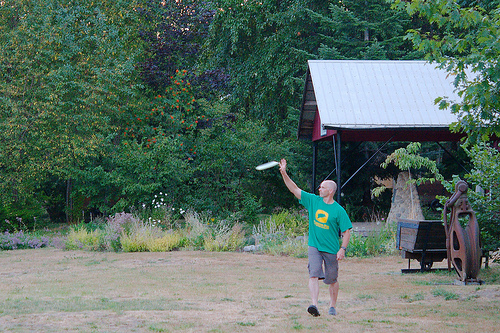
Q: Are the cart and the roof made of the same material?
A: No, the cart is made of wood and the roof is made of metal.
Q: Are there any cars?
A: No, there are no cars.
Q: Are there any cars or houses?
A: No, there are no cars or houses.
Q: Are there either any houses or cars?
A: No, there are no cars or houses.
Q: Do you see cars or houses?
A: No, there are no cars or houses.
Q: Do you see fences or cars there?
A: No, there are no cars or fences.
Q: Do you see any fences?
A: No, there are no fences.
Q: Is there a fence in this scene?
A: No, there are no fences.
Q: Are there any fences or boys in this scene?
A: No, there are no fences or boys.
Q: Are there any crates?
A: No, there are no crates.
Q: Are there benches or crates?
A: No, there are no crates or benches.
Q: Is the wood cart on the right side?
A: Yes, the cart is on the right of the image.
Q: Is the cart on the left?
A: No, the cart is on the right of the image.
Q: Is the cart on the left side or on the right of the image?
A: The cart is on the right of the image.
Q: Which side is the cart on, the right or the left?
A: The cart is on the right of the image.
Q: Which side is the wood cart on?
A: The cart is on the right of the image.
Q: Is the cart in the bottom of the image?
A: Yes, the cart is in the bottom of the image.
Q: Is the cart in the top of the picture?
A: No, the cart is in the bottom of the image.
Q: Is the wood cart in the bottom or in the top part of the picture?
A: The cart is in the bottom of the image.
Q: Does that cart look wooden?
A: Yes, the cart is wooden.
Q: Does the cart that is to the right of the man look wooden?
A: Yes, the cart is wooden.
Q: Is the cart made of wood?
A: Yes, the cart is made of wood.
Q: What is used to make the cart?
A: The cart is made of wood.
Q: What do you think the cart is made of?
A: The cart is made of wood.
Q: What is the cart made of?
A: The cart is made of wood.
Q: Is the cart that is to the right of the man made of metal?
A: No, the cart is made of wood.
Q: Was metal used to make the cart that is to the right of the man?
A: No, the cart is made of wood.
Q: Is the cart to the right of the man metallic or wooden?
A: The cart is wooden.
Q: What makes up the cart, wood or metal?
A: The cart is made of wood.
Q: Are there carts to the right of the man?
A: Yes, there is a cart to the right of the man.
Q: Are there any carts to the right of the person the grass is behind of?
A: Yes, there is a cart to the right of the man.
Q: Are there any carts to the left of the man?
A: No, the cart is to the right of the man.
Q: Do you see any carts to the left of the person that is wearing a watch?
A: No, the cart is to the right of the man.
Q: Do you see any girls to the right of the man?
A: No, there is a cart to the right of the man.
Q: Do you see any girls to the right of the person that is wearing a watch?
A: No, there is a cart to the right of the man.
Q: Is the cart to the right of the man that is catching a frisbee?
A: Yes, the cart is to the right of the man.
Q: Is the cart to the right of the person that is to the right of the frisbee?
A: Yes, the cart is to the right of the man.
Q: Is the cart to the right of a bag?
A: No, the cart is to the right of the man.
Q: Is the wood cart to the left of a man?
A: No, the cart is to the right of a man.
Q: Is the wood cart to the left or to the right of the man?
A: The cart is to the right of the man.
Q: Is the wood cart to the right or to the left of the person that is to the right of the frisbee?
A: The cart is to the right of the man.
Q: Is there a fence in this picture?
A: No, there are no fences.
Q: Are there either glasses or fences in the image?
A: No, there are no fences or glasses.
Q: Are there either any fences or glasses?
A: No, there are no fences or glasses.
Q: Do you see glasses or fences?
A: No, there are no fences or glasses.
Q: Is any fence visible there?
A: No, there are no fences.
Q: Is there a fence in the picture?
A: No, there are no fences.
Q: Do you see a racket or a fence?
A: No, there are no fences or rackets.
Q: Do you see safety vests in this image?
A: No, there are no safety vests.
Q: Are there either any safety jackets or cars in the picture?
A: No, there are no safety jackets or cars.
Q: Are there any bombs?
A: No, there are no bombs.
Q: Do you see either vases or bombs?
A: No, there are no bombs or vases.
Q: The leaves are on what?
A: The leaves are on the bushes.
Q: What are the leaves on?
A: The leaves are on the bushes.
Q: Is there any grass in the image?
A: Yes, there is grass.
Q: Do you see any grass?
A: Yes, there is grass.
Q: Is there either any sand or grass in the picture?
A: Yes, there is grass.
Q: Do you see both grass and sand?
A: No, there is grass but no sand.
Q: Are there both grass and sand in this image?
A: No, there is grass but no sand.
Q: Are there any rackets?
A: No, there are no rackets.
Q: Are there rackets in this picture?
A: No, there are no rackets.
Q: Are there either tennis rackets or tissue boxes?
A: No, there are no tennis rackets or tissue boxes.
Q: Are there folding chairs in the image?
A: No, there are no folding chairs.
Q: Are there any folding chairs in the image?
A: No, there are no folding chairs.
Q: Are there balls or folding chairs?
A: No, there are no folding chairs or balls.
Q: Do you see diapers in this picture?
A: No, there are no diapers.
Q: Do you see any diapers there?
A: No, there are no diapers.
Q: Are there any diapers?
A: No, there are no diapers.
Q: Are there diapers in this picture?
A: No, there are no diapers.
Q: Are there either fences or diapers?
A: No, there are no diapers or fences.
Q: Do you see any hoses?
A: No, there are no hoses.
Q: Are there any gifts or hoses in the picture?
A: No, there are no hoses or gifts.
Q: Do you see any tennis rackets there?
A: No, there are no tennis rackets.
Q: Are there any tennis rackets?
A: No, there are no tennis rackets.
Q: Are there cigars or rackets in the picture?
A: No, there are no rackets or cigars.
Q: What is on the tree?
A: The flowers are on the tree.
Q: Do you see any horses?
A: No, there are no horses.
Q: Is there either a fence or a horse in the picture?
A: No, there are no horses or fences.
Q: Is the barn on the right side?
A: Yes, the barn is on the right of the image.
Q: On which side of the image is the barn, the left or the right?
A: The barn is on the right of the image.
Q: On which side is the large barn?
A: The barn is on the right of the image.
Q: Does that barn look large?
A: Yes, the barn is large.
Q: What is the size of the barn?
A: The barn is large.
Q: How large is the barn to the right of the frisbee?
A: The barn is large.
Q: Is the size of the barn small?
A: No, the barn is large.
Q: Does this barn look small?
A: No, the barn is large.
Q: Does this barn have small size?
A: No, the barn is large.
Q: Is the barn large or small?
A: The barn is large.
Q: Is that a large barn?
A: Yes, that is a large barn.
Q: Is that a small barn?
A: No, that is a large barn.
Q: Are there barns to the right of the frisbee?
A: Yes, there is a barn to the right of the frisbee.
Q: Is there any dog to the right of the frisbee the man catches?
A: No, there is a barn to the right of the frisbee.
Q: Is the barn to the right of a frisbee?
A: Yes, the barn is to the right of a frisbee.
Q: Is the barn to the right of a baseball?
A: No, the barn is to the right of a frisbee.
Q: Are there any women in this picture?
A: No, there are no women.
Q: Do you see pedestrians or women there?
A: No, there are no women or pedestrians.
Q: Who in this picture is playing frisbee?
A: The man is playing frisbee.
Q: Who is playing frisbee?
A: The man is playing frisbee.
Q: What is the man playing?
A: The man is playing frisbee.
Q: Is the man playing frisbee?
A: Yes, the man is playing frisbee.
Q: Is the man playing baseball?
A: No, the man is playing frisbee.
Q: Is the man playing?
A: Yes, the man is playing.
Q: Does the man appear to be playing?
A: Yes, the man is playing.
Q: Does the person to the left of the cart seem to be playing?
A: Yes, the man is playing.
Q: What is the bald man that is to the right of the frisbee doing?
A: The man is playing.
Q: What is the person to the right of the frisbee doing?
A: The man is playing.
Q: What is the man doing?
A: The man is playing.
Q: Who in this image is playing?
A: The man is playing.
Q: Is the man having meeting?
A: No, the man is playing.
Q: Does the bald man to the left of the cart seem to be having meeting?
A: No, the man is playing.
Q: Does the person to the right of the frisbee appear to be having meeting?
A: No, the man is playing.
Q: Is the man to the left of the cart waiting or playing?
A: The man is playing.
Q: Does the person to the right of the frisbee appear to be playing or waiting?
A: The man is playing.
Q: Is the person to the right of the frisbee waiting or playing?
A: The man is playing.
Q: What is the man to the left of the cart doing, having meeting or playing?
A: The man is playing.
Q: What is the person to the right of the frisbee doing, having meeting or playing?
A: The man is playing.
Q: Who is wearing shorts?
A: The man is wearing shorts.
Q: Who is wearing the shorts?
A: The man is wearing shorts.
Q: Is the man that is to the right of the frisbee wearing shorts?
A: Yes, the man is wearing shorts.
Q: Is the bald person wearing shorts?
A: Yes, the man is wearing shorts.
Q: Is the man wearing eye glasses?
A: No, the man is wearing shorts.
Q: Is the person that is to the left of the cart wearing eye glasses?
A: No, the man is wearing shorts.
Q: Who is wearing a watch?
A: The man is wearing a watch.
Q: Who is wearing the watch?
A: The man is wearing a watch.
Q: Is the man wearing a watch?
A: Yes, the man is wearing a watch.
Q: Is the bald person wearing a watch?
A: Yes, the man is wearing a watch.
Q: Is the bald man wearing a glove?
A: No, the man is wearing a watch.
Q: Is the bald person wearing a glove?
A: No, the man is wearing a watch.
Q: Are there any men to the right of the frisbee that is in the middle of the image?
A: Yes, there is a man to the right of the frisbee.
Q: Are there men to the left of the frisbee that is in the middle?
A: No, the man is to the right of the frisbee.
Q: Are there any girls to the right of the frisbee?
A: No, there is a man to the right of the frisbee.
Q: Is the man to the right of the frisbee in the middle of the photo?
A: Yes, the man is to the right of the frisbee.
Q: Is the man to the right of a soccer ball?
A: No, the man is to the right of the frisbee.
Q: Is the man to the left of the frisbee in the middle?
A: No, the man is to the right of the frisbee.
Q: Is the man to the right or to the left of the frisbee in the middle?
A: The man is to the right of the frisbee.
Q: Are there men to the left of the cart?
A: Yes, there is a man to the left of the cart.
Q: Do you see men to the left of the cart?
A: Yes, there is a man to the left of the cart.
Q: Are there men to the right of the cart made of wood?
A: No, the man is to the left of the cart.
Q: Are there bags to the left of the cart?
A: No, there is a man to the left of the cart.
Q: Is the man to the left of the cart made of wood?
A: Yes, the man is to the left of the cart.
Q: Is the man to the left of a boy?
A: No, the man is to the left of the cart.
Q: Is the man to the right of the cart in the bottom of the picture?
A: No, the man is to the left of the cart.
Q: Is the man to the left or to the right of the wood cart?
A: The man is to the left of the cart.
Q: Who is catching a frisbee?
A: The man is catching a frisbee.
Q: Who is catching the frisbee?
A: The man is catching a frisbee.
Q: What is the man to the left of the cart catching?
A: The man is catching a frisbee.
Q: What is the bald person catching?
A: The man is catching a frisbee.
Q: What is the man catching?
A: The man is catching a frisbee.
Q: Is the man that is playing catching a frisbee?
A: Yes, the man is catching a frisbee.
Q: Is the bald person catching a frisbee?
A: Yes, the man is catching a frisbee.